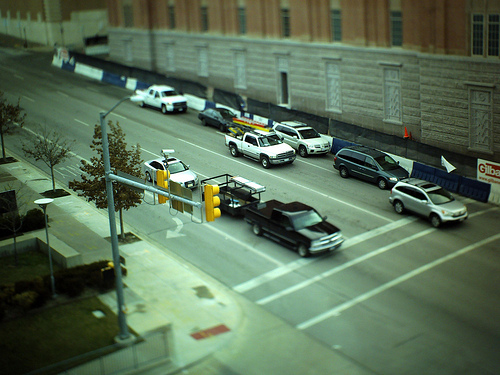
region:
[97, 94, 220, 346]
a street light with traffic lights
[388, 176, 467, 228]
a silver SUV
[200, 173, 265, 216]
a trailer behind the pickup truck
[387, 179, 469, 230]
car driving on paved road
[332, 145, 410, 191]
car driving on paved road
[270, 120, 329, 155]
car driving on paved road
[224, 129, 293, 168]
car driving on paved road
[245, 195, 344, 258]
car driving on paved road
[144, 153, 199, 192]
car driving on paved road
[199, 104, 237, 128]
car driving on paved road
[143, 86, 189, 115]
car driving on paved road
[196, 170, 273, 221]
black cart being pulled by truck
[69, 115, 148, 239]
tree on sidewalk near intersection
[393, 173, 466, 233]
car on a street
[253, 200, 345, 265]
truck on a street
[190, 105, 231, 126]
car on a street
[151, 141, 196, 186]
car on a street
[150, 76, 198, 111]
truck on a building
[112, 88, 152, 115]
light on a pole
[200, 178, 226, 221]
traffic light on a pole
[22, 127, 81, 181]
tree on a side walk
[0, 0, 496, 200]
building overlooking city street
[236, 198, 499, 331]
white line across street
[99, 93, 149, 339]
light on top of pole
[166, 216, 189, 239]
white arrow on street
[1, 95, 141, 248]
trees planted in sidewalk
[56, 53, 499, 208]
blue and white barriers along street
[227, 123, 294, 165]
front of white pickup truck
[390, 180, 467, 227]
vehicle with sun roof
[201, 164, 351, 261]
black truck with trailer attached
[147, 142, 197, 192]
silver car with sunlight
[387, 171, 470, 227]
silver sports utility vehicle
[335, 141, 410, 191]
black minvan car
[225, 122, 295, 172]
white pickup truck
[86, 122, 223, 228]
traffic lights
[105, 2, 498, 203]
multi story brick building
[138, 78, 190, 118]
White pickup truck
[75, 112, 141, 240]
tall green trees with leaves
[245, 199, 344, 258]
car driving in front of car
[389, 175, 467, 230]
car driving in front of car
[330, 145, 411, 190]
car driving in front of car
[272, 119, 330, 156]
car driving in front of car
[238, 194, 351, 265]
the car is color black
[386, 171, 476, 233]
the car is color gray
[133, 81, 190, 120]
the car is parkingon the road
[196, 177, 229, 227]
traffic light is yellow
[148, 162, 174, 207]
traffic light is yellow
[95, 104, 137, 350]
the pole is color gray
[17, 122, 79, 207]
the tree is on the sidewalk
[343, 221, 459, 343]
white lines on the road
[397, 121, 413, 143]
the cone is orange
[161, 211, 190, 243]
the arrow is white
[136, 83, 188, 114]
car driving on city street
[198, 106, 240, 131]
car driving on city street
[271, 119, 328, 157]
car driving on city street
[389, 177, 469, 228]
car driving on city street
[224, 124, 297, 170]
car driving on city street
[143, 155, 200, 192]
car driving on city street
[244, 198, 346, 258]
car driving on city street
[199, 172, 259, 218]
black cart behind truck